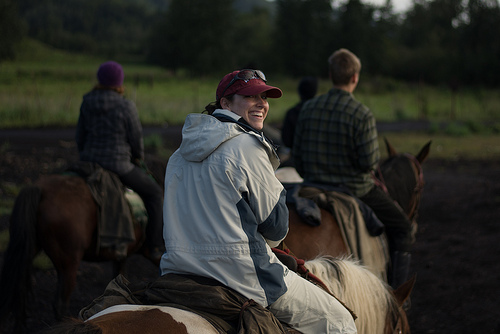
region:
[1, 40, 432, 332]
people riding horses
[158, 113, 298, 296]
a white and dark grey lightweight jacket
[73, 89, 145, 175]
a dark plaid jacket with hood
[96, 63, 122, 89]
a purple toboggan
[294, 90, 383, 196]
a green plaid flannel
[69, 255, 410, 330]
a brown and white horse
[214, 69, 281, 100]
a burgundy color ball cap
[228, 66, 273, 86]
a pair of sunglasses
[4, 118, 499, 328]
a dirt field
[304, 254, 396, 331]
white mane of horse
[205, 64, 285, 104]
red baseball cap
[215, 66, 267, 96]
pair of black sunglasses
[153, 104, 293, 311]
tan and gret hooded coat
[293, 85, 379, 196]
green plaid long sleeve shirt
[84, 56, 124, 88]
pruple knit hat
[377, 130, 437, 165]
two pointed horse ears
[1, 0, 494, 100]
tall green trees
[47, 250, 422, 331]
tan and brown horse with blonde man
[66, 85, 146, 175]
plaid hooded coat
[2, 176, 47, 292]
brown horse tail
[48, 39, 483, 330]
four people riding horses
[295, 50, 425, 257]
guy in a plaid shirt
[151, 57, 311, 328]
woman wearing a white jacket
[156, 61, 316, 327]
woman wearing a red hat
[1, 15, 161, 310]
woman on a horse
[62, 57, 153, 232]
woman wearing a purple hat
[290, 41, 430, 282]
guy riding a horse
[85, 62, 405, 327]
woman on a brown and white horse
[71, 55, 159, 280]
woman wearing a plaid jacket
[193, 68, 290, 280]
woman wearing a baseball cap and a beige jacket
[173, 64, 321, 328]
woman on horseback looking toward the camera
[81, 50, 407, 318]
group of four people riding horses outside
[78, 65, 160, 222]
woman wearing a purple hat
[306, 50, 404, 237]
man with a plaid shirt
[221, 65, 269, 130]
woman with a pair of sunglasses on top of her head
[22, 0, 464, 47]
trees in the background of the horseback riders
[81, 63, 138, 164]
woman wearing a purple stocking hat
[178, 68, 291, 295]
woman wearing a tan and blue hooded jacket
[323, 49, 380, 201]
blond haired man on horseback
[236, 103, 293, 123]
smile on woman's face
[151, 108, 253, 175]
tan hoodie on jacket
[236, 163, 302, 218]
line on the jacket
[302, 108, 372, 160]
green and black plaid shirt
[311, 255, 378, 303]
fur on horse's head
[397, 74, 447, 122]
fence on the side of the pathy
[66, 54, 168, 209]
woman riding brown horse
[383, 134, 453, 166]
perked up ears on horse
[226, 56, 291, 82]
sun glasses on cap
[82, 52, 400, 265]
riders on horses